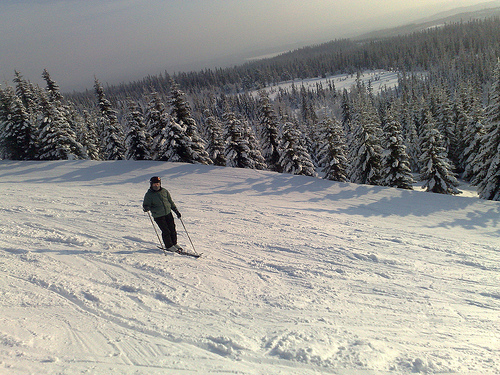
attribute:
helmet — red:
[146, 175, 163, 187]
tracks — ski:
[212, 212, 428, 334]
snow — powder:
[2, 160, 495, 374]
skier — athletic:
[141, 175, 183, 251]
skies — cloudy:
[4, 0, 272, 101]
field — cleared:
[5, 160, 498, 372]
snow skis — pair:
[154, 243, 202, 262]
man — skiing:
[126, 173, 219, 276]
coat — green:
[142, 182, 179, 222]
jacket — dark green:
[141, 180, 215, 235]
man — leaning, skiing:
[140, 175, 182, 251]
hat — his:
[146, 172, 161, 187]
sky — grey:
[1, 2, 499, 94]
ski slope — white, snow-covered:
[38, 184, 489, 355]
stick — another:
[148, 211, 172, 256]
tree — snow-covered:
[215, 95, 255, 166]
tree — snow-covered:
[247, 77, 288, 171]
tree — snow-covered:
[312, 109, 356, 181]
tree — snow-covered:
[350, 101, 390, 187]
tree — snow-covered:
[37, 69, 92, 154]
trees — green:
[9, 67, 497, 192]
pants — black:
[152, 210, 182, 247]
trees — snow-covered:
[2, 57, 499, 201]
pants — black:
[158, 215, 179, 245]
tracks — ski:
[30, 206, 106, 267]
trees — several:
[56, 86, 478, 168]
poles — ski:
[140, 207, 206, 256]